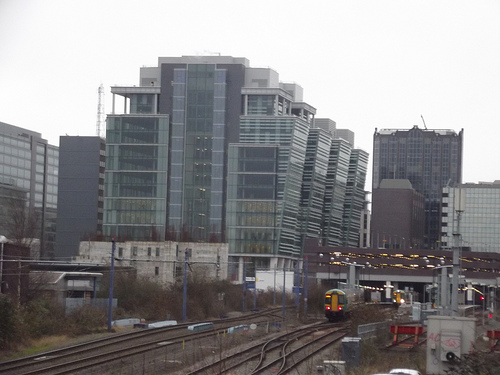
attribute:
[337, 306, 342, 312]
headlights — red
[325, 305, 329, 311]
headlights — red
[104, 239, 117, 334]
post — grey, tall, metal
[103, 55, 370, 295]
building — large, tall, under construction, high rise, graffitid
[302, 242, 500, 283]
garage — parking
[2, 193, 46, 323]
trees — brown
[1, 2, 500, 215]
sky — gray, cloudless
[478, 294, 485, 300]
light — red, railroad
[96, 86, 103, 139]
antenna — large, grey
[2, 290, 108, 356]
bushes — large, green, growing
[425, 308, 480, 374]
panel — grey, electric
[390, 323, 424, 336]
sign — red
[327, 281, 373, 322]
train — grey, yellow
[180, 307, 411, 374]
tracks — train, railroad, multiple, empty